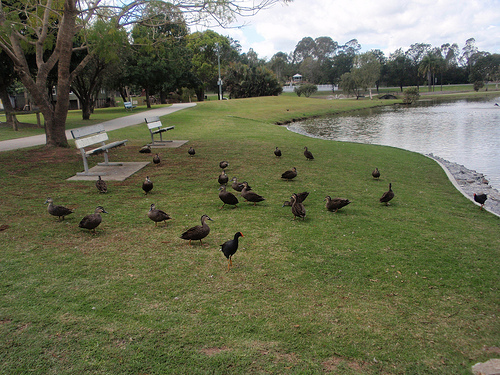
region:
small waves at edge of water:
[431, 144, 486, 189]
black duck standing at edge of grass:
[465, 179, 496, 220]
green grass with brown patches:
[52, 254, 444, 366]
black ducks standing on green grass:
[173, 124, 403, 269]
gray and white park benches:
[58, 102, 193, 224]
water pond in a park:
[280, 77, 489, 159]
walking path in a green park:
[4, 91, 200, 189]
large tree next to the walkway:
[0, 1, 118, 151]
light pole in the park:
[207, 40, 233, 102]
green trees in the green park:
[88, 5, 493, 96]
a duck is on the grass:
[178, 210, 213, 245]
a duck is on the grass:
[76, 203, 106, 233]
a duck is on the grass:
[40, 195, 73, 220]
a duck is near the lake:
[380, 179, 395, 204]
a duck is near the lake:
[302, 144, 318, 161]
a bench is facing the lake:
[67, 120, 122, 169]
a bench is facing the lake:
[141, 113, 173, 142]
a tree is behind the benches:
[10, 0, 256, 143]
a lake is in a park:
[278, 95, 494, 249]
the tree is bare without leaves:
[6, 0, 276, 159]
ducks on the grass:
[46, 101, 491, 279]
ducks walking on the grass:
[19, 114, 415, 300]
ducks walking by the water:
[61, 121, 494, 338]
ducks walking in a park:
[10, 97, 475, 311]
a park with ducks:
[41, 122, 486, 312]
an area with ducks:
[35, 118, 460, 288]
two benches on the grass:
[43, 111, 194, 190]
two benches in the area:
[29, 105, 244, 185]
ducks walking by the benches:
[36, 103, 471, 322]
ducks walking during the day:
[29, 124, 434, 335]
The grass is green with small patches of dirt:
[15, 267, 466, 340]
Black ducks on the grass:
[178, 208, 248, 266]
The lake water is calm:
[323, 110, 499, 132]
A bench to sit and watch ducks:
[67, 118, 135, 166]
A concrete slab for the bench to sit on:
[58, 151, 150, 190]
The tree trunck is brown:
[7, 40, 82, 148]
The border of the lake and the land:
[287, 124, 495, 224]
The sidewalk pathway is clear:
[68, 97, 209, 149]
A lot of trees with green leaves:
[79, 20, 283, 121]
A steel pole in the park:
[206, 45, 240, 105]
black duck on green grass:
[0, 228, 28, 262]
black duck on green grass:
[211, 231, 238, 262]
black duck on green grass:
[176, 213, 221, 253]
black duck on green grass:
[74, 203, 105, 237]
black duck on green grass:
[43, 191, 76, 222]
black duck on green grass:
[368, 180, 400, 218]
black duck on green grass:
[352, 155, 390, 187]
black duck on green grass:
[300, 142, 322, 177]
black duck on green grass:
[265, 138, 291, 165]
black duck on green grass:
[180, 145, 208, 167]